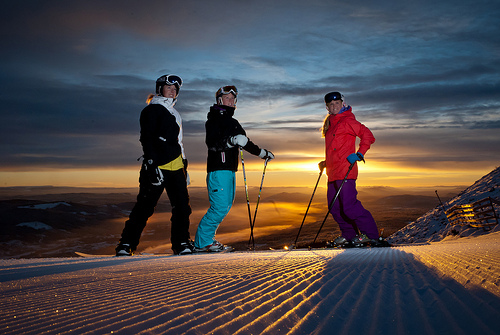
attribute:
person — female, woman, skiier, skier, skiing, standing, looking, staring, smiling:
[109, 53, 200, 265]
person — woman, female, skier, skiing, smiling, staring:
[188, 71, 283, 262]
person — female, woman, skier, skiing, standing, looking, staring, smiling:
[301, 71, 399, 253]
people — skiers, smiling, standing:
[113, 41, 405, 263]